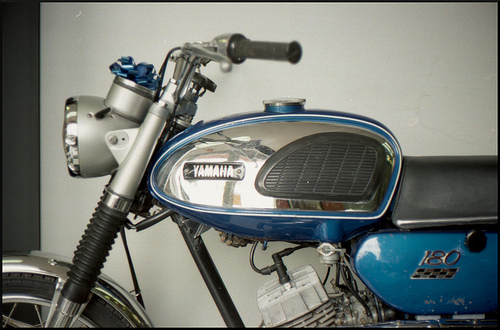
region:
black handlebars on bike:
[191, 14, 320, 82]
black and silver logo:
[180, 157, 239, 192]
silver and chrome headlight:
[58, 85, 121, 184]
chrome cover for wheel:
[15, 231, 141, 322]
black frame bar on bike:
[178, 225, 245, 325]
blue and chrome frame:
[182, 108, 492, 313]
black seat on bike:
[399, 125, 491, 223]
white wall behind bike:
[125, 4, 405, 89]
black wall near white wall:
[0, 14, 42, 164]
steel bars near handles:
[181, 27, 226, 126]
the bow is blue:
[107, 47, 174, 108]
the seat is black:
[431, 154, 491, 191]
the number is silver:
[416, 243, 463, 270]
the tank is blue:
[250, 217, 299, 237]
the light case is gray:
[81, 106, 108, 133]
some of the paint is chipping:
[424, 286, 474, 314]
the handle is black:
[228, 23, 303, 76]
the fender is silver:
[13, 254, 61, 278]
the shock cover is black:
[91, 194, 115, 276]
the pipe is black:
[186, 249, 240, 309]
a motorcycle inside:
[28, 15, 442, 328]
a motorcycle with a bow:
[33, 18, 423, 328]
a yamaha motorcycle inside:
[85, 18, 451, 328]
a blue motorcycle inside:
[10, 26, 435, 328]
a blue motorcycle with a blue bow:
[62, 25, 493, 315]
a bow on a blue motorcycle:
[19, 8, 424, 297]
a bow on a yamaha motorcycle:
[19, 23, 499, 308]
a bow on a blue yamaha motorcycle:
[17, 28, 494, 275]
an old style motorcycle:
[43, 23, 490, 291]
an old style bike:
[47, 30, 479, 322]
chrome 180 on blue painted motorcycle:
[420, 241, 462, 270]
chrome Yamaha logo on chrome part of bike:
[176, 155, 251, 186]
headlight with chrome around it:
[46, 85, 96, 190]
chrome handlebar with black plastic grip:
[163, 15, 313, 86]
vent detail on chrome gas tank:
[259, 121, 385, 213]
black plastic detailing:
[61, 200, 125, 302]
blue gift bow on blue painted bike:
[103, 50, 163, 97]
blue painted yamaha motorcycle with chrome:
[13, 20, 495, 328]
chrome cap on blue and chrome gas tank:
[253, 85, 311, 124]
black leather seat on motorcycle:
[393, 135, 483, 245]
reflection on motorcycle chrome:
[151, 136, 277, 236]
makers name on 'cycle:
[168, 155, 244, 191]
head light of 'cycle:
[53, 82, 111, 193]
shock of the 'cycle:
[54, 190, 137, 314]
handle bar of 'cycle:
[165, 32, 305, 93]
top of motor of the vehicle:
[275, 265, 345, 327]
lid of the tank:
[250, 92, 320, 110]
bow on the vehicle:
[107, 53, 160, 93]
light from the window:
[160, 126, 277, 232]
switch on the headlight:
[87, 100, 114, 130]